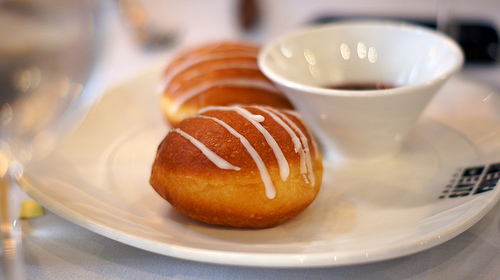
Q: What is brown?
A: Two pastries.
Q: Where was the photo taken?
A: At a cafe.